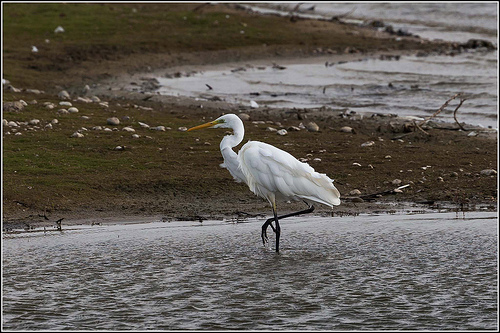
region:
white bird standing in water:
[169, 91, 349, 243]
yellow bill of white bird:
[194, 117, 213, 137]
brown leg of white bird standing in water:
[269, 207, 287, 250]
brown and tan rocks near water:
[16, 89, 153, 154]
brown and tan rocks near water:
[288, 121, 394, 151]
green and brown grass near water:
[20, 150, 197, 213]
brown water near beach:
[20, 232, 230, 312]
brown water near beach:
[312, 230, 467, 306]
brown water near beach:
[240, 77, 480, 92]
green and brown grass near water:
[30, 14, 241, 43]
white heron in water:
[188, 111, 339, 259]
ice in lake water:
[8, 228, 498, 327]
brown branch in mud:
[431, 96, 463, 131]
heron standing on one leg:
[190, 113, 340, 258]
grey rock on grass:
[55, 91, 72, 99]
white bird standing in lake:
[192, 115, 346, 258]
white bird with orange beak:
[183, 108, 339, 263]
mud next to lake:
[18, 193, 266, 221]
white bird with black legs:
[192, 112, 342, 257]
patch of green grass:
[6, 3, 251, 39]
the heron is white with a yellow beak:
[183, 110, 342, 262]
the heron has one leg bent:
[253, 187, 318, 268]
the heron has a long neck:
[196, 112, 246, 186]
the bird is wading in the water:
[171, 105, 356, 332]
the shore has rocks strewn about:
[21, 8, 495, 263]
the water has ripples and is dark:
[8, 240, 498, 330]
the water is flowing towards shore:
[142, 42, 494, 138]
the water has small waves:
[289, 0, 498, 56]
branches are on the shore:
[387, 90, 473, 142]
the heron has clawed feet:
[256, 219, 278, 254]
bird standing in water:
[152, 104, 358, 266]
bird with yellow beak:
[183, 116, 212, 136]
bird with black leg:
[270, 231, 290, 257]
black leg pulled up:
[256, 220, 273, 246]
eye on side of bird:
[216, 117, 229, 127]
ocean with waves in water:
[168, 272, 325, 312]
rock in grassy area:
[356, 137, 378, 149]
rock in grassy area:
[303, 121, 320, 134]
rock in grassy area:
[107, 115, 132, 128]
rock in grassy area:
[67, 105, 84, 112]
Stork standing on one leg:
[175, 102, 362, 267]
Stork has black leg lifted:
[247, 195, 319, 244]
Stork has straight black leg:
[266, 204, 288, 261]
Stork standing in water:
[187, 104, 369, 274]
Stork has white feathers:
[205, 105, 352, 219]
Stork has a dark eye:
[215, 105, 229, 128]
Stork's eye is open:
[215, 112, 230, 127]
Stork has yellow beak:
[181, 110, 223, 140]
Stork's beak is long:
[178, 114, 219, 139]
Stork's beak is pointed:
[179, 116, 227, 138]